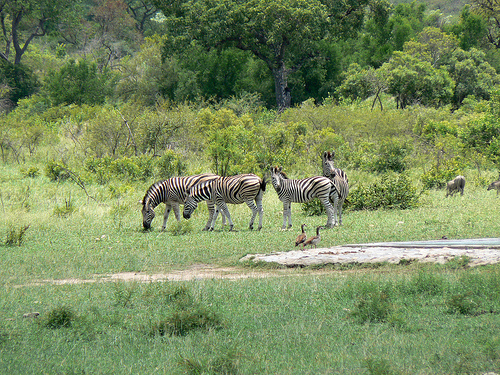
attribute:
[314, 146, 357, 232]
zebra — standing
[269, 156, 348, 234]
zebra — standing, looking, black, white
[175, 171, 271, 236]
zebra — standing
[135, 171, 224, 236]
zebra — standing, grazing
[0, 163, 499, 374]
grass — green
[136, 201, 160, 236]
head — bent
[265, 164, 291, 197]
head — tilted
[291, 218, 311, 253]
bird — walking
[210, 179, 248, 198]
stripes — black, white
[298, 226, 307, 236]
neck — black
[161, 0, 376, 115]
tree — large, green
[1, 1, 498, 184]
brush — overgrown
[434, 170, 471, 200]
zebra — grazing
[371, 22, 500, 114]
tree — small, short, green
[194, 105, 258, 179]
tree — small, short, green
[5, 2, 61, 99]
tree — green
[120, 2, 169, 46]
tree — green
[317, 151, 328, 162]
ear — pointed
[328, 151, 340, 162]
ear — pointed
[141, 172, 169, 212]
hair — short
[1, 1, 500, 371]
picture — daytime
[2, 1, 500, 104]
woods — grey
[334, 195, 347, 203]
hair — black